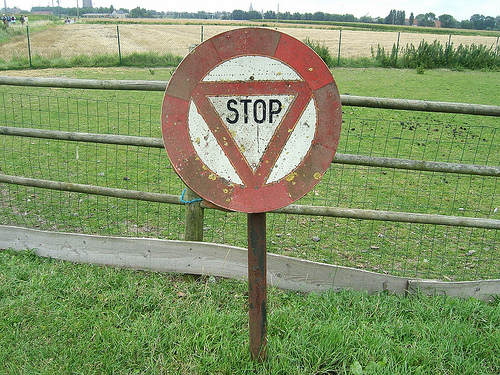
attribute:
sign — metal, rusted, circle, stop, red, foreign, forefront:
[152, 22, 363, 230]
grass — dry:
[375, 74, 423, 93]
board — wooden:
[48, 75, 143, 142]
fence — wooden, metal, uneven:
[15, 75, 126, 207]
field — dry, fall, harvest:
[70, 29, 130, 50]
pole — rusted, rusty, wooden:
[211, 224, 312, 358]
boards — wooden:
[110, 74, 158, 197]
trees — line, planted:
[283, 0, 431, 66]